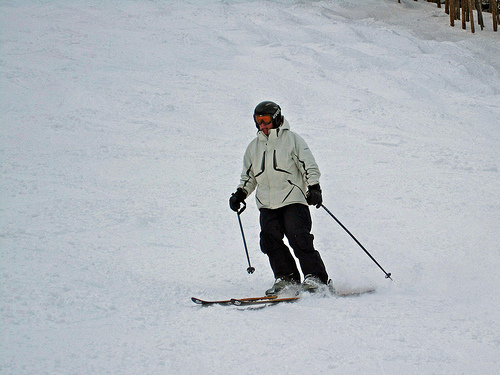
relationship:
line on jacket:
[272, 177, 309, 199] [232, 124, 324, 208]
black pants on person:
[258, 202, 328, 285] [228, 100, 330, 295]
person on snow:
[228, 100, 330, 295] [88, 71, 283, 232]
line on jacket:
[280, 184, 295, 206] [236, 126, 321, 207]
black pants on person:
[258, 202, 328, 285] [195, 80, 370, 322]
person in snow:
[195, 80, 370, 322] [117, 290, 499, 374]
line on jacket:
[253, 150, 265, 179] [238, 115, 321, 210]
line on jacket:
[270, 147, 293, 175] [238, 115, 321, 210]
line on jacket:
[243, 163, 252, 185] [238, 115, 321, 210]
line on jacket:
[288, 148, 314, 186] [229, 114, 327, 216]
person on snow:
[228, 100, 330, 295] [42, 21, 496, 343]